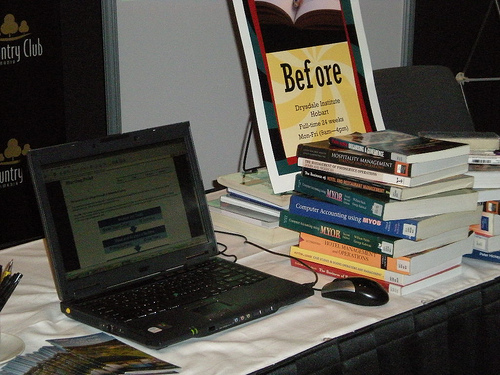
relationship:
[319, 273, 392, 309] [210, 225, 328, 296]
mouse with wire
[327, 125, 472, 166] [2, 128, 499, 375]
book on table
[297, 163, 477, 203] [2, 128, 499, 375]
book on table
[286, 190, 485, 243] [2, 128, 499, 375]
book on table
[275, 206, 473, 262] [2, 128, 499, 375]
book on table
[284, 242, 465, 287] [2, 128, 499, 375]
book on table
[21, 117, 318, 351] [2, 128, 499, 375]
laptop on table